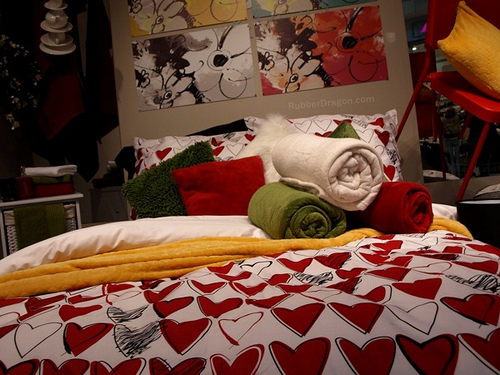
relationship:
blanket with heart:
[8, 211, 500, 374] [277, 303, 324, 333]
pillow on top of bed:
[176, 151, 267, 215] [1, 134, 499, 373]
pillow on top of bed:
[121, 141, 216, 220] [1, 134, 499, 373]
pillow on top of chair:
[442, 6, 500, 98] [396, 3, 500, 199]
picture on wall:
[127, 3, 389, 83] [113, 2, 433, 191]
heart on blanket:
[216, 314, 259, 340] [8, 211, 500, 374]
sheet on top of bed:
[431, 201, 459, 220] [1, 134, 499, 373]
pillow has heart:
[133, 130, 257, 169] [220, 140, 246, 154]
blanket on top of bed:
[271, 125, 379, 211] [1, 134, 499, 373]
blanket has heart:
[8, 211, 500, 374] [277, 303, 324, 333]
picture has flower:
[127, 3, 389, 83] [191, 28, 253, 96]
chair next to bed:
[396, 3, 500, 199] [1, 134, 499, 373]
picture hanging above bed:
[127, 3, 389, 83] [1, 134, 499, 373]